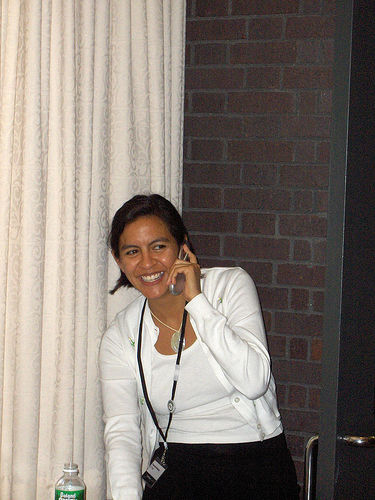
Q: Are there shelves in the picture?
A: No, there are no shelves.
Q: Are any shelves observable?
A: No, there are no shelves.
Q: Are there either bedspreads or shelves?
A: No, there are no shelves or bedspreads.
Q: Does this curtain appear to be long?
A: Yes, the curtain is long.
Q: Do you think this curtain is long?
A: Yes, the curtain is long.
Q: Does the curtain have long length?
A: Yes, the curtain is long.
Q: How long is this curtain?
A: The curtain is long.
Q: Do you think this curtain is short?
A: No, the curtain is long.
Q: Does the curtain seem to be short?
A: No, the curtain is long.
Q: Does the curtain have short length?
A: No, the curtain is long.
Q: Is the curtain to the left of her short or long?
A: The curtain is long.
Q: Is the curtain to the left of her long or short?
A: The curtain is long.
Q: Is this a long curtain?
A: Yes, this is a long curtain.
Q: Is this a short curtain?
A: No, this is a long curtain.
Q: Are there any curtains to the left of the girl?
A: Yes, there is a curtain to the left of the girl.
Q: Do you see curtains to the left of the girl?
A: Yes, there is a curtain to the left of the girl.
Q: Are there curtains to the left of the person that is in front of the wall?
A: Yes, there is a curtain to the left of the girl.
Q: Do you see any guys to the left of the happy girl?
A: No, there is a curtain to the left of the girl.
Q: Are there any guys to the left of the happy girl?
A: No, there is a curtain to the left of the girl.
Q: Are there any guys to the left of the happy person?
A: No, there is a curtain to the left of the girl.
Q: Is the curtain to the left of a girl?
A: Yes, the curtain is to the left of a girl.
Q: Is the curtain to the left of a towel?
A: No, the curtain is to the left of a girl.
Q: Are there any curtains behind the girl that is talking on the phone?
A: Yes, there is a curtain behind the girl.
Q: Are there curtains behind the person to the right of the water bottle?
A: Yes, there is a curtain behind the girl.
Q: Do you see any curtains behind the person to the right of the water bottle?
A: Yes, there is a curtain behind the girl.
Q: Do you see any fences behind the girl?
A: No, there is a curtain behind the girl.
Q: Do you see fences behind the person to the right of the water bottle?
A: No, there is a curtain behind the girl.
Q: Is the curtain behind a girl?
A: Yes, the curtain is behind a girl.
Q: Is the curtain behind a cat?
A: No, the curtain is behind a girl.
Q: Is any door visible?
A: Yes, there is a door.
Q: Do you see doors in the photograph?
A: Yes, there is a door.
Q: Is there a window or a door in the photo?
A: Yes, there is a door.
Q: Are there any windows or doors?
A: Yes, there is a door.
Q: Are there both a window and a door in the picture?
A: No, there is a door but no windows.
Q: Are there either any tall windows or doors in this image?
A: Yes, there is a tall door.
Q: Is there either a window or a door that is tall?
A: Yes, the door is tall.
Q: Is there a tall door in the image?
A: Yes, there is a tall door.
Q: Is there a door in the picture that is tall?
A: Yes, there is a door that is tall.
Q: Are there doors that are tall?
A: Yes, there is a door that is tall.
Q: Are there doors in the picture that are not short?
A: Yes, there is a tall door.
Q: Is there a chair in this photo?
A: No, there are no chairs.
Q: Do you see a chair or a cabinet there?
A: No, there are no chairs or cabinets.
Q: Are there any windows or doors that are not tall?
A: No, there is a door but it is tall.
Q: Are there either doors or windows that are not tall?
A: No, there is a door but it is tall.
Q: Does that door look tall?
A: Yes, the door is tall.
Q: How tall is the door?
A: The door is tall.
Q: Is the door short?
A: No, the door is tall.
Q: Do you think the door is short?
A: No, the door is tall.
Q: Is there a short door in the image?
A: No, there is a door but it is tall.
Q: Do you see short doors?
A: No, there is a door but it is tall.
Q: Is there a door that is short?
A: No, there is a door but it is tall.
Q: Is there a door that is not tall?
A: No, there is a door but it is tall.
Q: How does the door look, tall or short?
A: The door is tall.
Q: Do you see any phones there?
A: Yes, there is a phone.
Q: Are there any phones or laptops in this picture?
A: Yes, there is a phone.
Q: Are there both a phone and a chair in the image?
A: No, there is a phone but no chairs.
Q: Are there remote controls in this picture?
A: No, there are no remote controls.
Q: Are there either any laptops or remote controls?
A: No, there are no remote controls or laptops.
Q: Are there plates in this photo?
A: No, there are no plates.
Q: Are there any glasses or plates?
A: No, there are no plates or glasses.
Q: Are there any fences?
A: No, there are no fences.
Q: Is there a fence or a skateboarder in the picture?
A: No, there are no fences or skateboarders.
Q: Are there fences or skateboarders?
A: No, there are no fences or skateboarders.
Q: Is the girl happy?
A: Yes, the girl is happy.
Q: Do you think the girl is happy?
A: Yes, the girl is happy.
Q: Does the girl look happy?
A: Yes, the girl is happy.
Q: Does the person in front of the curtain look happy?
A: Yes, the girl is happy.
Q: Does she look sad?
A: No, the girl is happy.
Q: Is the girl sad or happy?
A: The girl is happy.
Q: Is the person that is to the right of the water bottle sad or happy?
A: The girl is happy.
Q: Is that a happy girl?
A: Yes, that is a happy girl.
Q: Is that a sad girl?
A: No, that is a happy girl.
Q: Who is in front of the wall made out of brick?
A: The girl is in front of the wall.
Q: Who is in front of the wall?
A: The girl is in front of the wall.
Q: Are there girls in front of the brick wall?
A: Yes, there is a girl in front of the wall.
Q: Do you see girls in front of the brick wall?
A: Yes, there is a girl in front of the wall.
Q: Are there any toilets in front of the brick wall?
A: No, there is a girl in front of the wall.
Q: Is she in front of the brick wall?
A: Yes, the girl is in front of the wall.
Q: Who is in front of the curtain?
A: The girl is in front of the curtain.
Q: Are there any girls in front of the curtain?
A: Yes, there is a girl in front of the curtain.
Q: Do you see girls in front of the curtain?
A: Yes, there is a girl in front of the curtain.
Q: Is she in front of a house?
A: No, the girl is in front of the curtain.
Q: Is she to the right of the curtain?
A: Yes, the girl is to the right of the curtain.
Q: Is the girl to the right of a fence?
A: No, the girl is to the right of the curtain.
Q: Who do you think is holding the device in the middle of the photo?
A: The girl is holding the phone.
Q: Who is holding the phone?
A: The girl is holding the phone.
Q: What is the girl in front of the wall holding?
A: The girl is holding the telephone.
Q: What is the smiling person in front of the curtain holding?
A: The girl is holding the telephone.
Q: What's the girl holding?
A: The girl is holding the telephone.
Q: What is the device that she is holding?
A: The device is a phone.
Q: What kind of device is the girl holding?
A: The girl is holding the phone.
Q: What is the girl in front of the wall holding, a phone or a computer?
A: The girl is holding a phone.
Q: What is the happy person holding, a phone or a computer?
A: The girl is holding a phone.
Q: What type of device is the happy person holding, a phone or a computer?
A: The girl is holding a phone.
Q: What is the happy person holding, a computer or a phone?
A: The girl is holding a phone.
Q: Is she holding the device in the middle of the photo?
A: Yes, the girl is holding the telephone.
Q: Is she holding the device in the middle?
A: Yes, the girl is holding the telephone.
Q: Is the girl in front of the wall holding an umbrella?
A: No, the girl is holding the telephone.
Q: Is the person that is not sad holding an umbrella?
A: No, the girl is holding the telephone.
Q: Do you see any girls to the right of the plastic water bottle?
A: Yes, there is a girl to the right of the water bottle.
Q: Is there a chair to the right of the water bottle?
A: No, there is a girl to the right of the water bottle.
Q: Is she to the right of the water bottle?
A: Yes, the girl is to the right of the water bottle.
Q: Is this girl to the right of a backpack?
A: No, the girl is to the right of the water bottle.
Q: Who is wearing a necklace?
A: The girl is wearing a necklace.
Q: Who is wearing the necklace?
A: The girl is wearing a necklace.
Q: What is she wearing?
A: The girl is wearing a necklace.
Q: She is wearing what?
A: The girl is wearing a necklace.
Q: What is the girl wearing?
A: The girl is wearing a necklace.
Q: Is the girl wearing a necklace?
A: Yes, the girl is wearing a necklace.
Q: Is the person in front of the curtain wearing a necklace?
A: Yes, the girl is wearing a necklace.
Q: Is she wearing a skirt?
A: No, the girl is wearing a necklace.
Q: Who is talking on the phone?
A: The girl is talking on the phone.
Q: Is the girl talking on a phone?
A: Yes, the girl is talking on a phone.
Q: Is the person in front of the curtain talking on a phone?
A: Yes, the girl is talking on a phone.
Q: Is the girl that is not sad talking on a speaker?
A: No, the girl is talking on a phone.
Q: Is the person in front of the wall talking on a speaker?
A: No, the girl is talking on a phone.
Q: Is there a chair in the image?
A: No, there are no chairs.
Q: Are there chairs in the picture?
A: No, there are no chairs.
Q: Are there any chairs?
A: No, there are no chairs.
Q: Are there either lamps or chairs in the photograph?
A: No, there are no chairs or lamps.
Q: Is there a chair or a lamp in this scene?
A: No, there are no chairs or lamps.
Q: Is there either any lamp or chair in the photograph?
A: No, there are no chairs or lamps.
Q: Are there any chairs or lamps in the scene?
A: No, there are no chairs or lamps.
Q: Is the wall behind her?
A: Yes, the wall is behind a girl.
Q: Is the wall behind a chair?
A: No, the wall is behind a girl.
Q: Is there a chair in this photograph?
A: No, there are no chairs.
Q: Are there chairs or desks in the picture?
A: No, there are no chairs or desks.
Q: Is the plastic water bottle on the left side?
A: Yes, the water bottle is on the left of the image.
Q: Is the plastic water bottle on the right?
A: No, the water bottle is on the left of the image.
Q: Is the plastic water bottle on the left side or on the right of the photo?
A: The water bottle is on the left of the image.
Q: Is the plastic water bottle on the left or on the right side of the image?
A: The water bottle is on the left of the image.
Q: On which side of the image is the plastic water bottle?
A: The water bottle is on the left of the image.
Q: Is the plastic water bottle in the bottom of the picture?
A: Yes, the water bottle is in the bottom of the image.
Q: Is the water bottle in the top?
A: No, the water bottle is in the bottom of the image.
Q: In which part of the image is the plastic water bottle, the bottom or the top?
A: The water bottle is in the bottom of the image.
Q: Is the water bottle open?
A: Yes, the water bottle is open.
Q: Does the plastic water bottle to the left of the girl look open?
A: Yes, the water bottle is open.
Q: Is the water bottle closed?
A: No, the water bottle is open.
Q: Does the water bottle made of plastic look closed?
A: No, the water bottle is open.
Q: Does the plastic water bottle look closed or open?
A: The water bottle is open.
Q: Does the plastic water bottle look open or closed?
A: The water bottle is open.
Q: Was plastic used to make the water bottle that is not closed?
A: Yes, the water bottle is made of plastic.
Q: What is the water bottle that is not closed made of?
A: The water bottle is made of plastic.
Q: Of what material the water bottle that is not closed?
A: The water bottle is made of plastic.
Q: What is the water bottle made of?
A: The water bottle is made of plastic.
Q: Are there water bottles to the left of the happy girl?
A: Yes, there is a water bottle to the left of the girl.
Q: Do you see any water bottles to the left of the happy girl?
A: Yes, there is a water bottle to the left of the girl.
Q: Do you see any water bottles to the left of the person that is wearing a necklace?
A: Yes, there is a water bottle to the left of the girl.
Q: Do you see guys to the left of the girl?
A: No, there is a water bottle to the left of the girl.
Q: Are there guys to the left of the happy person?
A: No, there is a water bottle to the left of the girl.